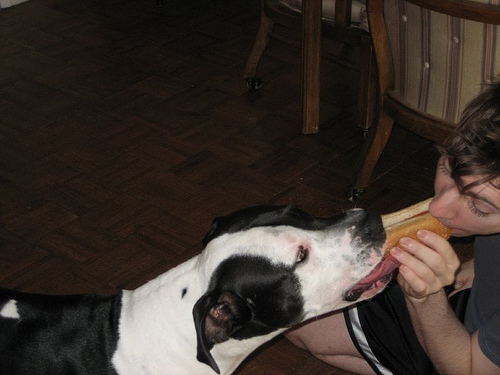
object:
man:
[280, 76, 500, 374]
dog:
[0, 201, 400, 375]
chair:
[231, 0, 383, 140]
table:
[340, 0, 500, 22]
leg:
[301, 1, 323, 135]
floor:
[1, 1, 500, 375]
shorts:
[338, 273, 483, 375]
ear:
[183, 285, 257, 375]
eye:
[295, 246, 311, 265]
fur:
[41, 310, 88, 362]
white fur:
[147, 301, 174, 338]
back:
[364, 2, 498, 151]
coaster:
[248, 76, 265, 91]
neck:
[127, 263, 264, 375]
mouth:
[427, 215, 470, 238]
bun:
[377, 197, 459, 261]